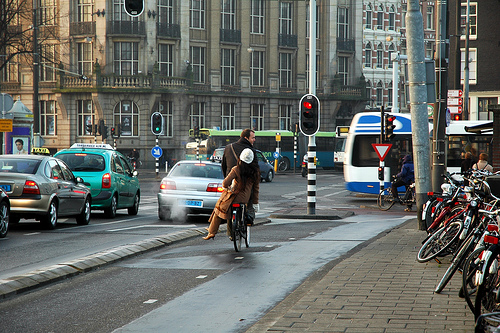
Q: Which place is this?
A: It is a street.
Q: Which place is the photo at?
A: It is at the street.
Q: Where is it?
A: This is at the street.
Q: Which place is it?
A: It is a street.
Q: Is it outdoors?
A: Yes, it is outdoors.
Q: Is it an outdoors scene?
A: Yes, it is outdoors.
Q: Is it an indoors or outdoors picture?
A: It is outdoors.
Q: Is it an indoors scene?
A: No, it is outdoors.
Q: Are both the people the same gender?
A: No, they are both male and female.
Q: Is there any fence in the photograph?
A: No, there are no fences.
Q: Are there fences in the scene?
A: No, there are no fences.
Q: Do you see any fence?
A: No, there are no fences.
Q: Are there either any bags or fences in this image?
A: No, there are no fences or bags.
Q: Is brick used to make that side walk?
A: Yes, the side walk is made of brick.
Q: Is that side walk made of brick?
A: Yes, the side walk is made of brick.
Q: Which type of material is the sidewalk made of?
A: The sidewalk is made of brick.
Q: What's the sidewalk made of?
A: The sidewalk is made of brick.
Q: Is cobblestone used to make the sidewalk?
A: No, the sidewalk is made of brick.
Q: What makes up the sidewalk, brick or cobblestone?
A: The sidewalk is made of brick.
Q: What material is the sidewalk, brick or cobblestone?
A: The sidewalk is made of brick.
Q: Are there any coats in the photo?
A: Yes, there is a coat.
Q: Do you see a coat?
A: Yes, there is a coat.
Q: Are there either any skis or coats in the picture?
A: Yes, there is a coat.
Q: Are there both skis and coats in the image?
A: No, there is a coat but no skis.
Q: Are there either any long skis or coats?
A: Yes, there is a long coat.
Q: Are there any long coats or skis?
A: Yes, there is a long coat.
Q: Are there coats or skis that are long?
A: Yes, the coat is long.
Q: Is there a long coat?
A: Yes, there is a long coat.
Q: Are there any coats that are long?
A: Yes, there is a coat that is long.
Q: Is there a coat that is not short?
A: Yes, there is a long coat.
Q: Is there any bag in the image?
A: No, there are no bags.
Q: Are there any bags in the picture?
A: No, there are no bags.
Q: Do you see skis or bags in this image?
A: No, there are no bags or skis.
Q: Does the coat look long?
A: Yes, the coat is long.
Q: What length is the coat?
A: The coat is long.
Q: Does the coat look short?
A: No, the coat is long.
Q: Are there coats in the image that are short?
A: No, there is a coat but it is long.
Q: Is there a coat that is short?
A: No, there is a coat but it is long.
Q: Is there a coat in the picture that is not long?
A: No, there is a coat but it is long.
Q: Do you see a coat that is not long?
A: No, there is a coat but it is long.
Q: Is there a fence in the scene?
A: No, there are no fences.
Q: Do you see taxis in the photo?
A: Yes, there is a taxi.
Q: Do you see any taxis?
A: Yes, there is a taxi.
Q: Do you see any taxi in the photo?
A: Yes, there is a taxi.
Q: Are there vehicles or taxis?
A: Yes, there is a taxi.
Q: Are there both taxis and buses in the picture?
A: Yes, there are both a taxi and a bus.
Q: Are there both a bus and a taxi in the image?
A: Yes, there are both a taxi and a bus.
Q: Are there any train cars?
A: No, there are no train cars.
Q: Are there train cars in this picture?
A: No, there are no train cars.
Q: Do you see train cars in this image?
A: No, there are no train cars.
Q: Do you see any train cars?
A: No, there are no train cars.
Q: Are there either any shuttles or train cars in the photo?
A: No, there are no train cars or shuttles.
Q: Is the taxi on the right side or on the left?
A: The taxi is on the left of the image.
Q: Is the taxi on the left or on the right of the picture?
A: The taxi is on the left of the image.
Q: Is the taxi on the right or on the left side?
A: The taxi is on the left of the image.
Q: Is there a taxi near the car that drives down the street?
A: Yes, there is a taxi near the car.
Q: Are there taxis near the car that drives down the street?
A: Yes, there is a taxi near the car.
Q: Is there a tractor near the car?
A: No, there is a taxi near the car.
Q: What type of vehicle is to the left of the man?
A: The vehicle is a taxi.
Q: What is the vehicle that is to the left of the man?
A: The vehicle is a taxi.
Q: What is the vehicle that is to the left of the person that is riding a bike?
A: The vehicle is a taxi.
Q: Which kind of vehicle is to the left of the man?
A: The vehicle is a taxi.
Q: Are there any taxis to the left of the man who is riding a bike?
A: Yes, there is a taxi to the left of the man.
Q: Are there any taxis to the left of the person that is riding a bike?
A: Yes, there is a taxi to the left of the man.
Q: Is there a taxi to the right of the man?
A: No, the taxi is to the left of the man.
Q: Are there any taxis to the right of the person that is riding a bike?
A: No, the taxi is to the left of the man.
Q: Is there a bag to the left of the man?
A: No, there is a taxi to the left of the man.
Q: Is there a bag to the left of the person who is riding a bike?
A: No, there is a taxi to the left of the man.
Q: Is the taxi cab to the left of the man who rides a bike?
A: Yes, the taxi cab is to the left of the man.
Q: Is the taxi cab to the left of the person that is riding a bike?
A: Yes, the taxi cab is to the left of the man.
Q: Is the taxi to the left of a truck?
A: No, the taxi is to the left of the man.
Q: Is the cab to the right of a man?
A: No, the cab is to the left of a man.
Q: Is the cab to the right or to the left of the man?
A: The cab is to the left of the man.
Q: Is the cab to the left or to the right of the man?
A: The cab is to the left of the man.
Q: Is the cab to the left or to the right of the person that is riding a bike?
A: The cab is to the left of the man.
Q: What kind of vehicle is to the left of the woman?
A: The vehicle is a taxi.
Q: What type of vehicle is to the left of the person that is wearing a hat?
A: The vehicle is a taxi.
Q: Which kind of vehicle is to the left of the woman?
A: The vehicle is a taxi.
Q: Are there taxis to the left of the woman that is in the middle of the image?
A: Yes, there is a taxi to the left of the woman.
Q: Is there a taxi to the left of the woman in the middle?
A: Yes, there is a taxi to the left of the woman.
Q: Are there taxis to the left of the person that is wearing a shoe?
A: Yes, there is a taxi to the left of the woman.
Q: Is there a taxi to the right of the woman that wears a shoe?
A: No, the taxi is to the left of the woman.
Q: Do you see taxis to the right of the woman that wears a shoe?
A: No, the taxi is to the left of the woman.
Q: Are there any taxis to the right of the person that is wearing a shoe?
A: No, the taxi is to the left of the woman.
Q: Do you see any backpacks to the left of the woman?
A: No, there is a taxi to the left of the woman.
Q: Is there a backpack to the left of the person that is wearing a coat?
A: No, there is a taxi to the left of the woman.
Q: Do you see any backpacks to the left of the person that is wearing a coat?
A: No, there is a taxi to the left of the woman.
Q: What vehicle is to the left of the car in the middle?
A: The vehicle is a taxi.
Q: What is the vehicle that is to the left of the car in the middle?
A: The vehicle is a taxi.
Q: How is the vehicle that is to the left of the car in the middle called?
A: The vehicle is a taxi.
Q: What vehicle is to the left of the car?
A: The vehicle is a taxi.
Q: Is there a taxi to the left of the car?
A: Yes, there is a taxi to the left of the car.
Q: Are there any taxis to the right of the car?
A: No, the taxi is to the left of the car.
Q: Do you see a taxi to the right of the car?
A: No, the taxi is to the left of the car.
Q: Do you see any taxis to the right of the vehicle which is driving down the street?
A: No, the taxi is to the left of the car.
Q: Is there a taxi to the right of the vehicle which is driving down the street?
A: No, the taxi is to the left of the car.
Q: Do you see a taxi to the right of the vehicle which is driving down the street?
A: No, the taxi is to the left of the car.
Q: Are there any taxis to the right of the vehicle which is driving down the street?
A: No, the taxi is to the left of the car.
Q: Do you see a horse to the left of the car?
A: No, there is a taxi to the left of the car.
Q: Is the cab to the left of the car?
A: Yes, the cab is to the left of the car.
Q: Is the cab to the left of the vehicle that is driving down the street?
A: Yes, the cab is to the left of the car.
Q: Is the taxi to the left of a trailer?
A: No, the taxi is to the left of the car.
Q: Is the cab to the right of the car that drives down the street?
A: No, the cab is to the left of the car.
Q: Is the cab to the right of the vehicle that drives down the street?
A: No, the cab is to the left of the car.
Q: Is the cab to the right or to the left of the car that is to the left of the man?
A: The cab is to the left of the car.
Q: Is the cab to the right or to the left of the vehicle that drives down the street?
A: The cab is to the left of the car.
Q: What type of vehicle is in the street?
A: The vehicle is a taxi.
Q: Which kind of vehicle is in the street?
A: The vehicle is a taxi.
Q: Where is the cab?
A: The cab is in the street.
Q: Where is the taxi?
A: The cab is in the street.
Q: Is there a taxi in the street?
A: Yes, there is a taxi in the street.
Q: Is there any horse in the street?
A: No, there is a taxi in the street.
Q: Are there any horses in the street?
A: No, there is a taxi in the street.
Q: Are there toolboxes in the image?
A: No, there are no toolboxes.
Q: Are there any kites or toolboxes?
A: No, there are no toolboxes or kites.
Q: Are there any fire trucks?
A: No, there are no fire trucks.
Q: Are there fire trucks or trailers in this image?
A: No, there are no fire trucks or trailers.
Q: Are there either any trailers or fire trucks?
A: No, there are no fire trucks or trailers.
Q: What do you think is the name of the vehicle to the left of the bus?
A: The vehicle is a car.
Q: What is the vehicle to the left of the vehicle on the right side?
A: The vehicle is a car.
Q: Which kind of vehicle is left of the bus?
A: The vehicle is a car.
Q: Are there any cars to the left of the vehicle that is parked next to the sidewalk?
A: Yes, there is a car to the left of the bus.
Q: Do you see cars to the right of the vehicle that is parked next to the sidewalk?
A: No, the car is to the left of the bus.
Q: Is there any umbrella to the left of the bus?
A: No, there is a car to the left of the bus.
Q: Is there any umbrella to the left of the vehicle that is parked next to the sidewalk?
A: No, there is a car to the left of the bus.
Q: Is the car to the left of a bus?
A: Yes, the car is to the left of a bus.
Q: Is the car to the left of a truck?
A: No, the car is to the left of a bus.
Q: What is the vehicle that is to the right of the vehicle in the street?
A: The vehicle is a car.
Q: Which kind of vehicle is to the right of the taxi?
A: The vehicle is a car.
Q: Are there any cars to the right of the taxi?
A: Yes, there is a car to the right of the taxi.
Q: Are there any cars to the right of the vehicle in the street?
A: Yes, there is a car to the right of the taxi.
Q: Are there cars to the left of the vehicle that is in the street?
A: No, the car is to the right of the cab.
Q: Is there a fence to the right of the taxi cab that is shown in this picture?
A: No, there is a car to the right of the taxi cab.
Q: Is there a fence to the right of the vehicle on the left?
A: No, there is a car to the right of the taxi cab.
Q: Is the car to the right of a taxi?
A: Yes, the car is to the right of a taxi.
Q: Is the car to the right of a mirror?
A: No, the car is to the right of a taxi.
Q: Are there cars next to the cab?
A: Yes, there is a car next to the cab.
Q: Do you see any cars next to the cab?
A: Yes, there is a car next to the cab.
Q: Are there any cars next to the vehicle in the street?
A: Yes, there is a car next to the cab.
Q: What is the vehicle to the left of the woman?
A: The vehicle is a car.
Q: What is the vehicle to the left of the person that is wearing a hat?
A: The vehicle is a car.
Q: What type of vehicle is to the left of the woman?
A: The vehicle is a car.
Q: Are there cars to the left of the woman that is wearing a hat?
A: Yes, there is a car to the left of the woman.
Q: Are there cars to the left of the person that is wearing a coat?
A: Yes, there is a car to the left of the woman.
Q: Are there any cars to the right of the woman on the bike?
A: No, the car is to the left of the woman.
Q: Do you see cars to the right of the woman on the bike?
A: No, the car is to the left of the woman.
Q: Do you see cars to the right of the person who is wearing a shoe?
A: No, the car is to the left of the woman.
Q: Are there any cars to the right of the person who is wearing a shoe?
A: No, the car is to the left of the woman.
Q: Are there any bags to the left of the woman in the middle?
A: No, there is a car to the left of the woman.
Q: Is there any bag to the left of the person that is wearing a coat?
A: No, there is a car to the left of the woman.